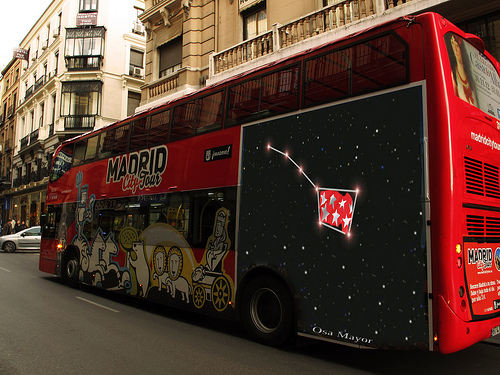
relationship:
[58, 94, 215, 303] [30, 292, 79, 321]
bus on street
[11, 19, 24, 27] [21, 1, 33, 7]
clouds are in sky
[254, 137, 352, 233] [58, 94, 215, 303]
dipper attached to bus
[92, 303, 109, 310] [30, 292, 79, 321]
line painted on street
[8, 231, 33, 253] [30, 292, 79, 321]
car on street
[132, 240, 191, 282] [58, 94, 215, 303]
osa mayor attached to bus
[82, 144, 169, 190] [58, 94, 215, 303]
madrid city tour on bus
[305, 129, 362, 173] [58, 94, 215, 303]
mural on bus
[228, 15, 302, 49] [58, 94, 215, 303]
balconies are above bus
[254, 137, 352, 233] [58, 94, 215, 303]
dipper on bus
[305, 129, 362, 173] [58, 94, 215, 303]
mural on side of bus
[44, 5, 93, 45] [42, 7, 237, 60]
apartments are on buildings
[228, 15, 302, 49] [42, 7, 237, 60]
balconies inside buildings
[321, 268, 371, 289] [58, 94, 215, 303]
constellation on bus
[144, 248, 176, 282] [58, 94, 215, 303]
lions attached to bus